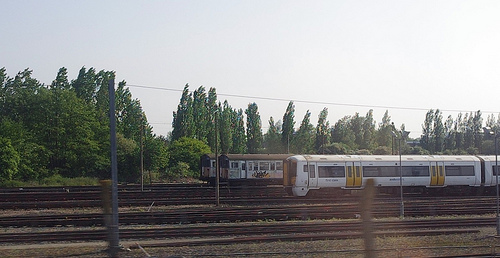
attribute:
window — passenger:
[355, 162, 432, 179]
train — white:
[270, 145, 497, 208]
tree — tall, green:
[174, 84, 197, 174]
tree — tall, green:
[191, 85, 212, 165]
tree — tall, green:
[208, 86, 218, 163]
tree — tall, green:
[280, 98, 297, 160]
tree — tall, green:
[246, 102, 263, 152]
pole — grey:
[100, 73, 142, 237]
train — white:
[159, 125, 491, 227]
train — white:
[278, 152, 498, 201]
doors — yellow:
[341, 162, 453, 186]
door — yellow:
[342, 157, 364, 190]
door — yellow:
[425, 155, 446, 189]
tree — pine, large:
[169, 75, 196, 135]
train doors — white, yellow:
[344, 161, 361, 185]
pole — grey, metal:
[102, 69, 126, 256]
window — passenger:
[315, 159, 348, 184]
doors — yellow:
[340, 164, 365, 194]